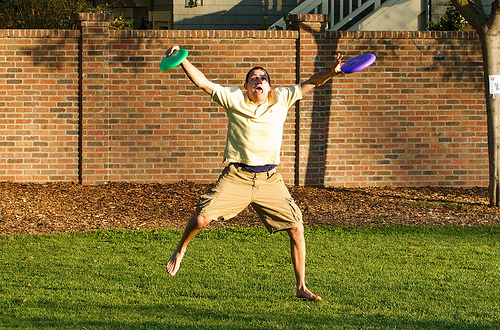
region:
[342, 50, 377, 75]
a purple frisbee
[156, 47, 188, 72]
a green frisbee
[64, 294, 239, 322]
a well manicured lawn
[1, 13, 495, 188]
a brick wall in background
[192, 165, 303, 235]
a pair of beige khaki shorts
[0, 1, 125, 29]
a tree in the background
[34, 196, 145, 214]
brown mulch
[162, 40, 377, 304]
A guy with two Frisbee's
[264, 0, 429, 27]
white wooden stair case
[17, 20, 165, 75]
shadow of tree on wall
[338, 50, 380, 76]
a blue Frisbee in the air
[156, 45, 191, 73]
a green Frisbee in the man's hand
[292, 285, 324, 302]
the foot of a man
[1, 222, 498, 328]
a green grassy lawn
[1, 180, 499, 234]
a patch of wood chips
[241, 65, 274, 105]
the head of a man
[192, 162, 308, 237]
a pair of brown shorts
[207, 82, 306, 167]
a yellow tee shirt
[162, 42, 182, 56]
the hand of a man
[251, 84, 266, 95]
the mouth of a man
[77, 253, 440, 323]
the grass is green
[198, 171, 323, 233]
the shorts are brown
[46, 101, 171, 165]
the walls are made of brick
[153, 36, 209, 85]
the frisbee is green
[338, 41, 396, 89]
the frisbee is purple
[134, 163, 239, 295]
the leg is up in the air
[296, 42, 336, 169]
there is a tree shadow on the wall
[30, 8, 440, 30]
there are buildings behind the wall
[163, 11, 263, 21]
the walls are grey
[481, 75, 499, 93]
there is picture on the tree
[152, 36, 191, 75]
The green Frisbee in the guy's left hand.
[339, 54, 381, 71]
The purple Frisbee in the guy's right hand.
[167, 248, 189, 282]
The guy's left foot.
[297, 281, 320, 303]
The guy's right foot.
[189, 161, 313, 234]
The beige pants the guy is wearing.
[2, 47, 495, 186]
The brick wall behind the guy with the Frisbees.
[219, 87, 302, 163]
The yellow shirt the guy has on.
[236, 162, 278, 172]
The guy's dark blue boxers.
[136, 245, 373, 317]
The grass area where the guy is standing.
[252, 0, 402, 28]
The white stairs in the background.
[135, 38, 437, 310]
A bare foot person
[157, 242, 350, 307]
Two bare feet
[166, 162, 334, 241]
A pair of tan shorts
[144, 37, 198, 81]
A hand holding a green Frisbee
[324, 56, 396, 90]
A hand catching a purple Frisbee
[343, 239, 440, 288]
Green grass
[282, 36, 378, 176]
A shadow on a brick wall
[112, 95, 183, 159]
A brick wall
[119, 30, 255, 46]
The top of a brick wall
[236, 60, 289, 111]
The head of a person